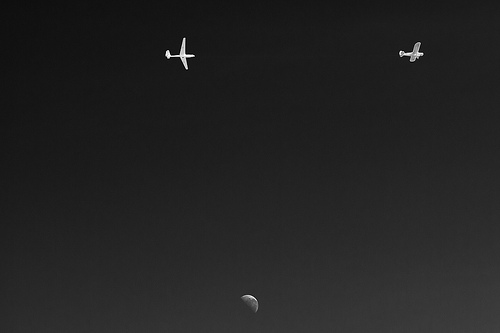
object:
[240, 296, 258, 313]
shadow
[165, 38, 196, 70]
airplane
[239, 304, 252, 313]
part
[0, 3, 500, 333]
dark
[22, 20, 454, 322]
sky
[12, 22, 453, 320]
photo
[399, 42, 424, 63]
angle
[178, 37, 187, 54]
wing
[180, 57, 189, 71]
wing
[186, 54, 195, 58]
nose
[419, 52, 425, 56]
nose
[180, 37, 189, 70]
wingspan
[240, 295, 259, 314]
moon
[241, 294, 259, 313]
lunar eclipse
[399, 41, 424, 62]
airplane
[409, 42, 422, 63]
wings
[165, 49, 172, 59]
tail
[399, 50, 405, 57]
tail